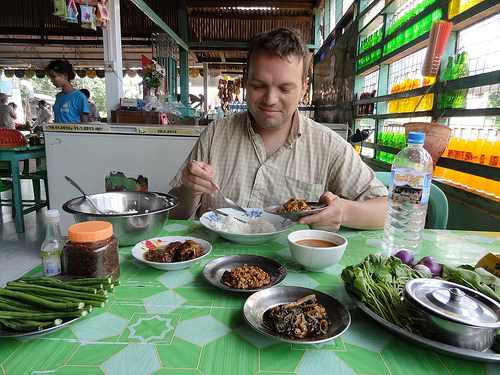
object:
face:
[243, 50, 309, 129]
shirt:
[50, 88, 90, 125]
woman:
[43, 60, 91, 123]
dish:
[0, 275, 97, 339]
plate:
[352, 291, 499, 364]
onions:
[394, 250, 442, 278]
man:
[163, 27, 388, 235]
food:
[340, 250, 500, 354]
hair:
[245, 27, 307, 86]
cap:
[407, 132, 427, 145]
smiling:
[256, 106, 283, 117]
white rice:
[208, 211, 277, 233]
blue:
[249, 210, 264, 219]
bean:
[0, 276, 121, 334]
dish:
[404, 278, 500, 353]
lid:
[403, 269, 499, 332]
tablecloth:
[172, 314, 233, 347]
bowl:
[62, 190, 180, 247]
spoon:
[193, 159, 247, 214]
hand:
[181, 160, 220, 196]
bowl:
[198, 208, 299, 246]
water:
[381, 176, 432, 258]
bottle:
[381, 131, 433, 258]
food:
[143, 213, 340, 340]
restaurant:
[0, 0, 500, 375]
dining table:
[0, 219, 500, 375]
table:
[0, 219, 500, 374]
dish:
[131, 235, 213, 270]